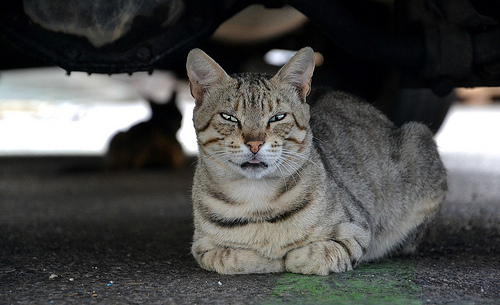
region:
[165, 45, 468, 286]
the cat is resting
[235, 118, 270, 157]
cat's nose is pink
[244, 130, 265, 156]
cat's nose is pink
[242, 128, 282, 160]
cat's nose is pink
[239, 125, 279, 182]
cat's nose is pink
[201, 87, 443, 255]
A brown big cat on the floor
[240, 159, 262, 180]
A brown big cat's mouth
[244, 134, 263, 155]
A brown big cat's nose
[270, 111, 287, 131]
A brown big cat's eye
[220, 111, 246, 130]
A brown big cat's eye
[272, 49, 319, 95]
A brown big cat's ear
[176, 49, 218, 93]
A brown big cat's ear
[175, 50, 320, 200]
A brown big cat's head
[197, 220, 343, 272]
A brown big cat's feet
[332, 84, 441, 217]
A brown big cat's fur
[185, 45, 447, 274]
A gray cat with black stripes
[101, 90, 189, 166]
The shadowy indistinct outline of a cat lying down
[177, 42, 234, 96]
A single cat's ear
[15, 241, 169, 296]
A portion of asphalt lightly littered with debris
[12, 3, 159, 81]
The indistinct undercarriage of a motor vehicle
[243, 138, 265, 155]
A cat's pinkish nose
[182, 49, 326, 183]
A cat with a challenging expression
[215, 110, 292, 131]
The thin, slitted eyes of a cat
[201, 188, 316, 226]
A quartet of stripes on a cat's light gray fur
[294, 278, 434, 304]
A portion of asphalt stained green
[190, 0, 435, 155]
the head of a cat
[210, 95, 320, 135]
th eyes of a cat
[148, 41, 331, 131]
the ears of a cat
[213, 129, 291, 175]
the nose of a cat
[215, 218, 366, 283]
the legs of a cat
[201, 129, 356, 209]
the mouth of a cat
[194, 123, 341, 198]
the whiskers of a cat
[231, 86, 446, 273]
the body of a cat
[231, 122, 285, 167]
a pink nose of a cat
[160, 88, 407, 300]
a cat under a car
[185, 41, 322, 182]
head of a cat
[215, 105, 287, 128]
eyes of a cat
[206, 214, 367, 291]
paws of a cat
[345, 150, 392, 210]
fur of a cat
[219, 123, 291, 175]
mouth of a cat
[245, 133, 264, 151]
nose of a cat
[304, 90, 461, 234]
body of a cat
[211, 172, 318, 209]
neck of a cat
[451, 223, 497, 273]
shadows of a cat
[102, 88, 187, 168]
cat under a car